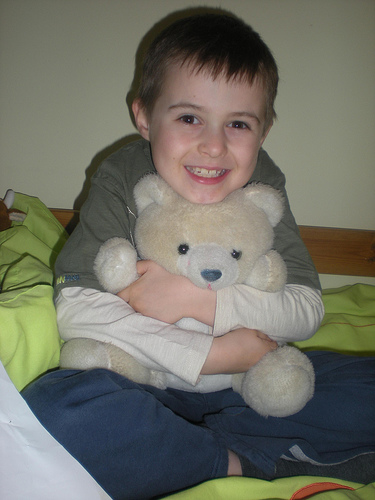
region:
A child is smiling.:
[130, 12, 277, 195]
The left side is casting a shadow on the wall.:
[46, 6, 231, 273]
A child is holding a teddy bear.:
[92, 174, 315, 417]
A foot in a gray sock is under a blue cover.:
[228, 446, 373, 484]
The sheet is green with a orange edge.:
[0, 189, 372, 497]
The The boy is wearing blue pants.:
[19, 348, 374, 499]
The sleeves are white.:
[55, 287, 323, 384]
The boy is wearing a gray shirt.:
[52, 139, 322, 295]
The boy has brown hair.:
[134, 11, 277, 139]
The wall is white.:
[1, 0, 373, 227]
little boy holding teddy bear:
[20, 4, 371, 483]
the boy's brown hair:
[127, 18, 302, 82]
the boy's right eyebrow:
[165, 100, 212, 117]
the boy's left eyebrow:
[230, 104, 258, 123]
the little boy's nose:
[201, 117, 221, 162]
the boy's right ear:
[127, 95, 147, 140]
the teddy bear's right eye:
[172, 235, 191, 251]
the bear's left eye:
[226, 242, 241, 257]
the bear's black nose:
[196, 266, 221, 281]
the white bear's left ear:
[249, 185, 283, 217]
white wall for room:
[286, 0, 374, 178]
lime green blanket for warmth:
[327, 291, 374, 349]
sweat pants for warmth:
[80, 391, 180, 469]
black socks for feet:
[244, 459, 374, 474]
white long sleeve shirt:
[59, 285, 202, 377]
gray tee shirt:
[91, 179, 131, 227]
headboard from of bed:
[319, 230, 365, 276]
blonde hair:
[149, 36, 279, 90]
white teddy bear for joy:
[133, 181, 286, 287]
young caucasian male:
[130, 10, 276, 202]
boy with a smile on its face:
[174, 156, 238, 191]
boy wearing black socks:
[239, 441, 372, 487]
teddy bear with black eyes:
[171, 239, 200, 259]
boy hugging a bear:
[94, 236, 286, 369]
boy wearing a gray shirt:
[83, 146, 141, 274]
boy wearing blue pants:
[39, 369, 348, 454]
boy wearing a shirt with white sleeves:
[213, 296, 320, 326]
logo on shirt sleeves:
[50, 269, 92, 293]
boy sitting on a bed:
[65, 133, 342, 419]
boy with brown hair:
[117, 17, 283, 123]